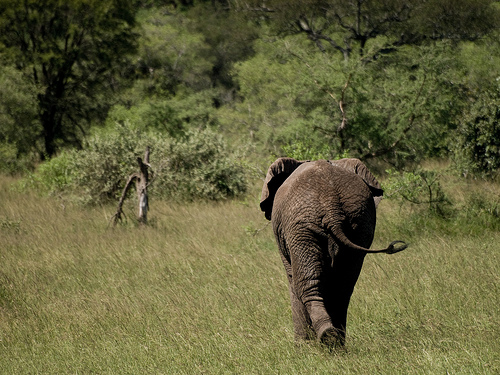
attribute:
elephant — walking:
[218, 137, 405, 342]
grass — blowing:
[399, 200, 490, 312]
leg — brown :
[292, 233, 335, 345]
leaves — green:
[191, 44, 208, 72]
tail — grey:
[326, 208, 433, 280]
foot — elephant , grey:
[309, 323, 346, 353]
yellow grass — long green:
[130, 236, 245, 317]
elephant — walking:
[252, 148, 388, 355]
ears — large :
[252, 151, 385, 222]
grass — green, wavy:
[167, 310, 284, 370]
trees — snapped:
[68, 128, 200, 230]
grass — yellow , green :
[113, 232, 284, 329]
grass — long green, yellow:
[30, 225, 272, 348]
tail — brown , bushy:
[324, 220, 408, 255]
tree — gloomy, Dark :
[29, 22, 189, 187]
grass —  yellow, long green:
[3, 174, 498, 374]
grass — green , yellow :
[20, 207, 495, 373]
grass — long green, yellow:
[23, 180, 495, 368]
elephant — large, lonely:
[258, 119, 391, 348]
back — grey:
[290, 159, 372, 202]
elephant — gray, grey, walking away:
[257, 154, 409, 349]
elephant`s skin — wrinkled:
[259, 157, 404, 347]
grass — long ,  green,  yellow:
[5, 236, 499, 370]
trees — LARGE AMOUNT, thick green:
[0, 1, 499, 199]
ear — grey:
[246, 151, 308, 224]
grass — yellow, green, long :
[1, 196, 498, 372]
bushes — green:
[33, 96, 346, 152]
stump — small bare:
[129, 148, 159, 260]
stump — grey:
[113, 187, 157, 226]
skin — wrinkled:
[315, 221, 336, 278]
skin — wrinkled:
[287, 164, 362, 288]